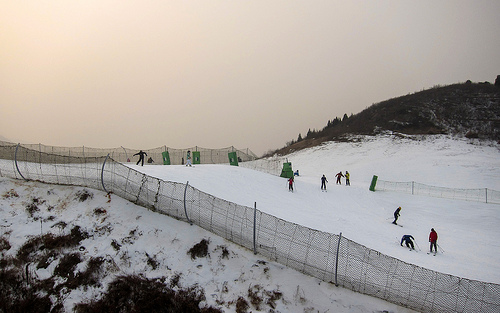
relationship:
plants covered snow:
[8, 196, 193, 298] [177, 167, 286, 211]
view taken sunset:
[9, 121, 465, 311] [8, 7, 221, 143]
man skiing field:
[390, 202, 408, 229] [167, 136, 484, 274]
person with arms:
[426, 228, 438, 256] [334, 170, 347, 189]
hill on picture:
[288, 80, 477, 217] [4, 3, 484, 304]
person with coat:
[426, 228, 445, 256] [429, 233, 439, 242]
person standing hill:
[426, 228, 438, 256] [250, 81, 484, 256]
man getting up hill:
[392, 206, 402, 225] [274, 77, 484, 230]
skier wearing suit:
[280, 164, 444, 254] [427, 232, 440, 247]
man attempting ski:
[392, 206, 402, 225] [394, 229, 425, 260]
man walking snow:
[392, 206, 402, 225] [270, 184, 288, 210]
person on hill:
[128, 145, 152, 173] [164, 157, 266, 207]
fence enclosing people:
[0, 143, 500, 312] [384, 199, 445, 254]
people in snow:
[400, 234, 415, 251] [320, 200, 372, 231]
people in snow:
[400, 234, 415, 251] [315, 198, 370, 231]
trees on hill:
[319, 112, 359, 135] [382, 95, 483, 129]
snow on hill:
[3, 130, 495, 311] [352, 88, 484, 144]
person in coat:
[426, 228, 438, 256] [429, 231, 438, 242]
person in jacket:
[426, 228, 438, 256] [425, 230, 439, 245]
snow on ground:
[3, 130, 495, 311] [2, 129, 498, 311]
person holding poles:
[426, 228, 438, 256] [434, 243, 444, 253]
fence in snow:
[4, 147, 474, 310] [3, 130, 495, 311]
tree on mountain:
[327, 120, 331, 127] [257, 77, 498, 163]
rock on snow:
[185, 235, 211, 261] [3, 130, 495, 311]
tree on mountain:
[340, 113, 349, 123] [257, 77, 498, 163]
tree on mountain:
[325, 116, 333, 126] [257, 77, 498, 163]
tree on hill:
[297, 130, 301, 144] [0, 75, 500, 313]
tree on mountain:
[286, 135, 296, 147] [257, 77, 498, 163]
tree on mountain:
[304, 123, 314, 136] [236, 77, 498, 186]